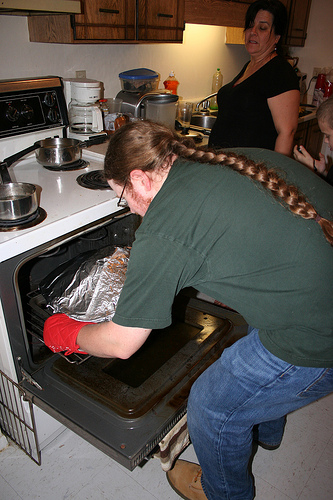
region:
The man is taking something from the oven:
[40, 119, 320, 404]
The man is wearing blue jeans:
[185, 323, 331, 494]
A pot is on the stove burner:
[26, 130, 108, 173]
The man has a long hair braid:
[163, 117, 331, 250]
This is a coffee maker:
[60, 68, 108, 134]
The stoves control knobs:
[4, 87, 63, 129]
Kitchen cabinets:
[42, 3, 190, 48]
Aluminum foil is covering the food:
[37, 241, 152, 319]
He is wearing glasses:
[98, 152, 160, 225]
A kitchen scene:
[5, 5, 327, 479]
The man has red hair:
[90, 110, 297, 253]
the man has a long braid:
[80, 101, 328, 282]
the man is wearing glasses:
[83, 96, 299, 318]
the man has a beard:
[88, 137, 281, 321]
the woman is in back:
[216, 12, 299, 173]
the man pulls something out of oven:
[9, 136, 268, 438]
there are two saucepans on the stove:
[19, 111, 221, 377]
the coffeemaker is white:
[28, 75, 134, 158]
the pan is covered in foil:
[18, 206, 244, 421]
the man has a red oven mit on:
[31, 299, 185, 394]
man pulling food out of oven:
[2, 97, 330, 469]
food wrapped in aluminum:
[25, 240, 161, 332]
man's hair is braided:
[93, 109, 317, 261]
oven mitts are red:
[16, 288, 120, 373]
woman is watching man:
[184, 0, 308, 159]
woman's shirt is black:
[201, 54, 311, 154]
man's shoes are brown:
[167, 452, 213, 498]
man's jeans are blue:
[168, 299, 331, 489]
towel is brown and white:
[139, 388, 212, 469]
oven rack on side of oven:
[0, 368, 65, 464]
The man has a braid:
[156, 116, 332, 277]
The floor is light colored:
[31, 457, 141, 498]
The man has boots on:
[141, 440, 280, 495]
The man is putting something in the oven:
[27, 251, 201, 349]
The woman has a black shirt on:
[200, 47, 327, 160]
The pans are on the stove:
[11, 107, 125, 230]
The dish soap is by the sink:
[137, 53, 221, 167]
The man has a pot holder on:
[36, 299, 141, 421]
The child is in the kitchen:
[288, 78, 332, 185]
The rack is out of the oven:
[0, 374, 57, 477]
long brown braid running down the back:
[179, 146, 332, 229]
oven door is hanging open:
[28, 289, 246, 481]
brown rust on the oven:
[54, 368, 138, 414]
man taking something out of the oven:
[31, 114, 330, 495]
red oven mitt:
[35, 314, 91, 358]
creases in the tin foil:
[103, 266, 116, 290]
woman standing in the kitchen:
[189, 3, 296, 161]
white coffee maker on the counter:
[57, 70, 114, 145]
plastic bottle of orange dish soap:
[163, 69, 179, 95]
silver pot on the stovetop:
[32, 127, 112, 169]